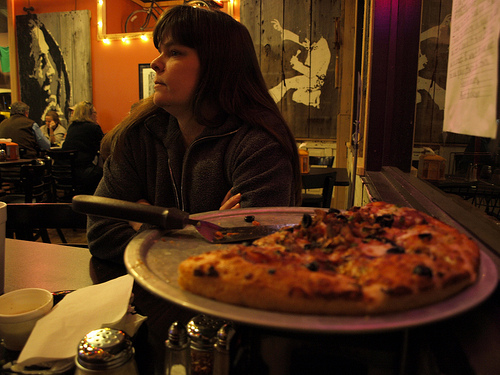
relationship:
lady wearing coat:
[88, 4, 302, 374] [86, 109, 303, 285]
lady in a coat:
[88, 4, 302, 374] [92, 112, 293, 272]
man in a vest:
[0, 97, 47, 162] [3, 113, 39, 158]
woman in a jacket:
[36, 104, 68, 149] [31, 123, 66, 147]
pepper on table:
[185, 311, 237, 373] [2, 237, 496, 373]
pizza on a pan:
[176, 201, 480, 315] [91, 177, 452, 324]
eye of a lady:
[165, 45, 199, 71] [88, 4, 302, 374]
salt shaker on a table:
[73, 326, 142, 373] [1, 285, 499, 373]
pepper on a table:
[186, 313, 237, 375] [2, 237, 496, 373]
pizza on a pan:
[173, 189, 490, 314] [125, 206, 498, 336]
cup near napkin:
[1, 285, 56, 350] [10, 270, 132, 367]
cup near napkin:
[1, 285, 56, 350] [117, 305, 147, 335]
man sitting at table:
[0, 102, 52, 160] [2, 237, 496, 373]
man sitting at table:
[0, 102, 52, 160] [12, 138, 73, 162]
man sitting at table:
[0, 102, 52, 160] [287, 157, 352, 192]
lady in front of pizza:
[88, 4, 302, 374] [173, 189, 490, 314]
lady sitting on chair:
[109, 27, 289, 259] [8, 157, 76, 240]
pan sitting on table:
[125, 206, 498, 336] [299, 167, 352, 202]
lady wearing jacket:
[88, 4, 302, 374] [99, 99, 301, 200]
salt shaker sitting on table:
[164, 320, 188, 372] [18, 213, 482, 364]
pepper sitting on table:
[186, 313, 237, 375] [18, 213, 482, 364]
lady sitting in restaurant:
[88, 4, 302, 374] [277, 1, 482, 371]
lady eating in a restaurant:
[88, 4, 302, 374] [277, 1, 482, 371]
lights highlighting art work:
[90, 1, 376, 61] [92, 1, 152, 55]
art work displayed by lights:
[92, 1, 152, 55] [90, 1, 376, 61]